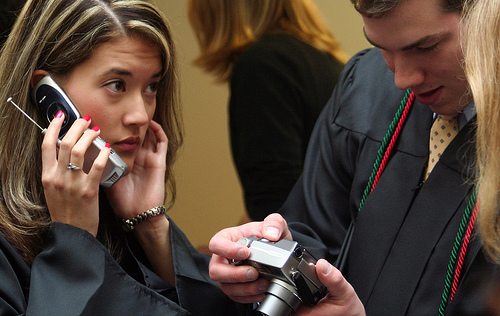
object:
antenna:
[6, 96, 59, 147]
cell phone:
[26, 75, 132, 188]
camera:
[221, 231, 331, 315]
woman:
[0, 0, 219, 314]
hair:
[452, 0, 499, 267]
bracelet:
[120, 203, 171, 234]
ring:
[65, 163, 81, 172]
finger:
[86, 141, 114, 182]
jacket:
[0, 212, 228, 316]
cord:
[354, 88, 417, 211]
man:
[206, 0, 497, 315]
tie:
[421, 113, 461, 181]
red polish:
[91, 125, 101, 132]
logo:
[36, 94, 48, 105]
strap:
[283, 274, 323, 309]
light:
[260, 238, 276, 244]